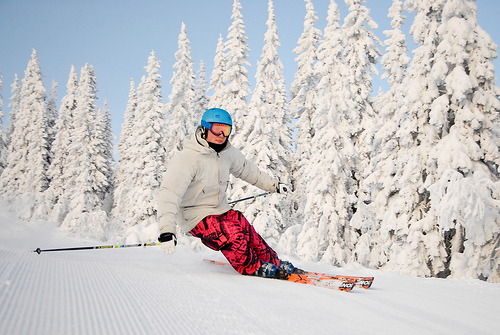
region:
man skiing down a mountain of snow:
[24, 109, 379, 322]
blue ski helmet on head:
[200, 107, 238, 130]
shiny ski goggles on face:
[201, 120, 235, 139]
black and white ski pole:
[35, 238, 155, 257]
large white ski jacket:
[138, 148, 294, 229]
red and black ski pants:
[201, 208, 274, 275]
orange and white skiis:
[286, 263, 364, 294]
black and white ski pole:
[226, 188, 276, 200]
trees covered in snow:
[331, 10, 470, 296]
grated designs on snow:
[12, 259, 131, 334]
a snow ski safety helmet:
[198, 107, 230, 135]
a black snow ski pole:
[30, 240, 165, 255]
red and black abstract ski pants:
[187, 205, 274, 270]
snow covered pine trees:
[0, 0, 497, 107]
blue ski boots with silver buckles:
[253, 262, 278, 279]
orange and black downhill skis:
[291, 266, 373, 291]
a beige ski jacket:
[157, 125, 277, 232]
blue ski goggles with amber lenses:
[206, 121, 231, 137]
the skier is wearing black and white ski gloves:
[157, 232, 177, 254]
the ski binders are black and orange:
[276, 268, 288, 280]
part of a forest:
[443, 143, 449, 149]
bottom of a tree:
[348, 197, 382, 259]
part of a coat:
[159, 203, 179, 239]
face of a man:
[205, 75, 231, 152]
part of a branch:
[409, 224, 419, 241]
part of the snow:
[174, 279, 204, 308]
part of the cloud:
[112, 103, 117, 120]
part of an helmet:
[210, 138, 213, 150]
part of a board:
[323, 265, 334, 283]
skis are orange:
[280, 254, 377, 301]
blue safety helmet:
[191, 109, 242, 124]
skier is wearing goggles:
[203, 120, 241, 138]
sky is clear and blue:
[30, 10, 156, 45]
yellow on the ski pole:
[92, 242, 158, 248]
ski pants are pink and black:
[212, 205, 269, 273]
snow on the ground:
[55, 282, 165, 320]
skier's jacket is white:
[177, 161, 230, 206]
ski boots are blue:
[253, 248, 303, 278]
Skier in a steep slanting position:
[25, 105, 378, 294]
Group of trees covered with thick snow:
[0, 1, 498, 278]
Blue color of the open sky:
[1, 0, 146, 50]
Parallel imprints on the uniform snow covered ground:
[2, 242, 238, 331]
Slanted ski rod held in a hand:
[25, 231, 184, 258]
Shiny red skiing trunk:
[184, 207, 284, 274]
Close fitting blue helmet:
[198, 107, 236, 130]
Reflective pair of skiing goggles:
[200, 123, 236, 138]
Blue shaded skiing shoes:
[256, 259, 297, 280]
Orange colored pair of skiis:
[292, 267, 381, 297]